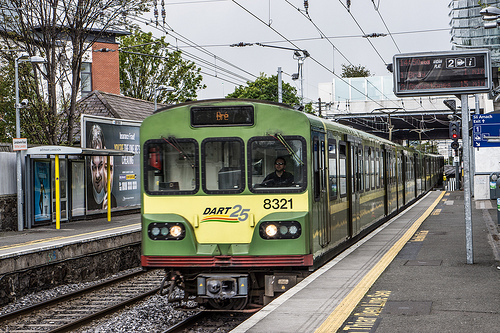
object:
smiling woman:
[87, 125, 109, 205]